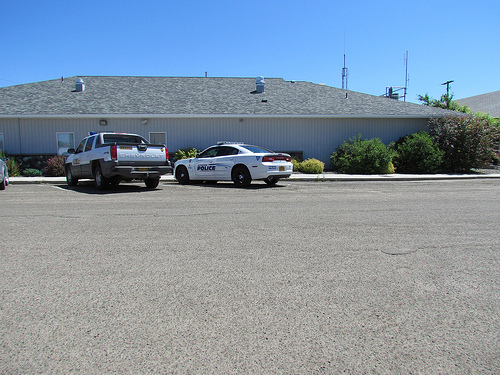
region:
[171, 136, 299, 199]
Police car parked in parking lot.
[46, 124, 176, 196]
Police truck parked in parking lot.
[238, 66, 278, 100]
Vent on top of roof.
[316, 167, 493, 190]
Sidewalk running on side of building.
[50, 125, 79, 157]
Window on side of building.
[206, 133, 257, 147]
Blue lights on top of police car.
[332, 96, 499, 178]
Shrubs growing on side of building.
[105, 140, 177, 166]
Break lights on back of police truck.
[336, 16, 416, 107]
communication antennas on top of building's roof.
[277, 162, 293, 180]
Tag on back of police car.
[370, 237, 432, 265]
small line on road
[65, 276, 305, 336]
large gray road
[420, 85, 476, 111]
top of green trees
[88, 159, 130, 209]
black wheels on truck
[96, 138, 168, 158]
red light on back of white truck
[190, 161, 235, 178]
bold letters on white car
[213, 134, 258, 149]
sirens on top of white car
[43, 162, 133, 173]
yellow parking line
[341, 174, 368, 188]
edge of white side walk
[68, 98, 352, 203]
cars parked in spaces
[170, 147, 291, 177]
A white police car parked in a parking lot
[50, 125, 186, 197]
White cheverolet truck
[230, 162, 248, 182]
wheel on the police car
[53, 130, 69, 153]
window on the exterior of the building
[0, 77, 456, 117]
roof on top of the building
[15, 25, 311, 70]
the blue sky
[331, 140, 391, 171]
bush near other bushes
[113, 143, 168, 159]
tailgate on the truck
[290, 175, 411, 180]
The curb next to the sidewalk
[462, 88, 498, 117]
A small mountain in the background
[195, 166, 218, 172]
The word POLICE on the side of the white car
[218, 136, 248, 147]
The panel of lights on top of the roof of the police car.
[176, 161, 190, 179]
The front tire of the police car.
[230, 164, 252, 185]
The back wheel on the driver's side of the police car.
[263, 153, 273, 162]
The left back brake light on the police car.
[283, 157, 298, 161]
The right brake light of the police car.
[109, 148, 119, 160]
The left back brake light on the pickup truck.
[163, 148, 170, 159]
The right back brake light on the truck.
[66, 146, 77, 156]
The side view mirror on the truck.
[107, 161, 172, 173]
The back bumper of the truck.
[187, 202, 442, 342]
this is the road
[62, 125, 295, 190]
these are some cars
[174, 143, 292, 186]
this is a police car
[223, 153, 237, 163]
the car is white in color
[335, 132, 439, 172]
these are some hedges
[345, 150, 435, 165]
the leaves are green in color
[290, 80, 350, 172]
this is a house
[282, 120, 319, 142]
the wall is white in color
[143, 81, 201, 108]
this is the house roof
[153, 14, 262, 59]
this is the blue sky